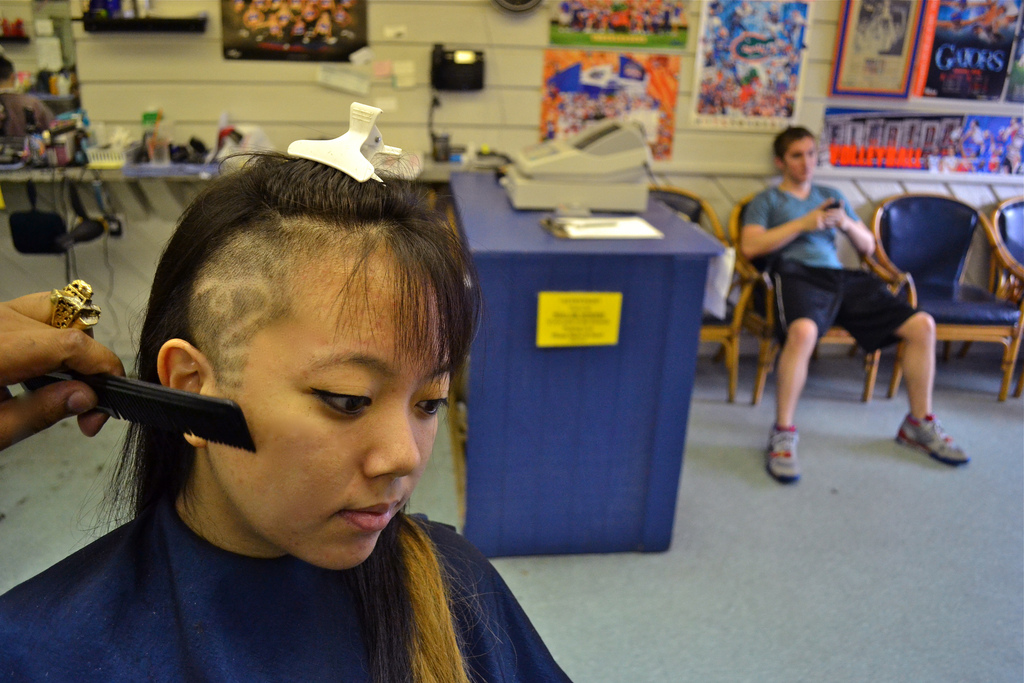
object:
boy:
[738, 127, 969, 486]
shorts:
[772, 261, 921, 350]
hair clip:
[286, 102, 403, 183]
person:
[0, 161, 544, 678]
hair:
[140, 156, 475, 530]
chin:
[306, 524, 381, 572]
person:
[0, 278, 123, 451]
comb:
[90, 374, 256, 452]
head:
[194, 218, 453, 570]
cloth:
[5, 515, 575, 683]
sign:
[536, 291, 621, 347]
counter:
[455, 177, 727, 558]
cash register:
[504, 120, 649, 212]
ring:
[50, 279, 101, 329]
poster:
[539, 50, 676, 162]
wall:
[5, 2, 1016, 359]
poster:
[690, 6, 810, 130]